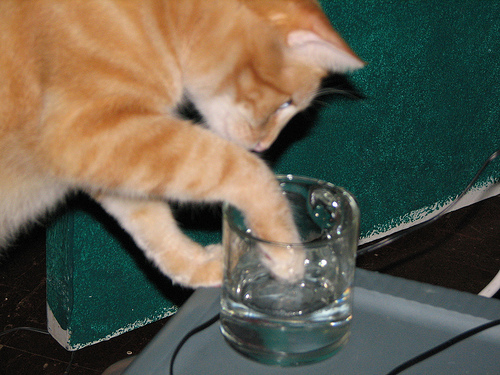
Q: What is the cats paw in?
A: A glass.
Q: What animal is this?
A: Cat.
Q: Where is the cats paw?
A: In the glass.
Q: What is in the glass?
A: Water.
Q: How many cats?
A: 1.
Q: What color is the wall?
A: Green.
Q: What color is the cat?
A: Orange and white.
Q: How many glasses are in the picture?
A: 1.